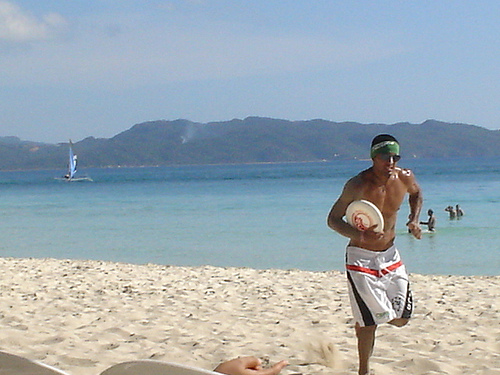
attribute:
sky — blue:
[0, 1, 498, 145]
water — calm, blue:
[18, 170, 498, 257]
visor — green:
[363, 127, 407, 164]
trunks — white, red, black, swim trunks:
[329, 241, 440, 315]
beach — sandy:
[24, 253, 498, 373]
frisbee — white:
[338, 198, 386, 241]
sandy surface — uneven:
[58, 240, 268, 357]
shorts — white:
[338, 236, 408, 342]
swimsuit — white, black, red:
[343, 245, 414, 325]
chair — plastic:
[96, 358, 224, 373]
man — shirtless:
[325, 133, 425, 372]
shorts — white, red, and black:
[331, 242, 424, 329]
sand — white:
[59, 312, 230, 362]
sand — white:
[166, 283, 294, 357]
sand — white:
[109, 242, 225, 358]